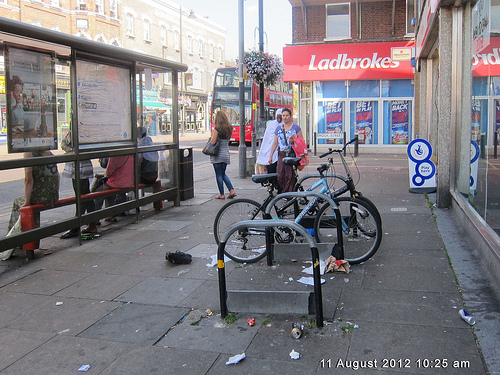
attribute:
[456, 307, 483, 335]
bottle — empty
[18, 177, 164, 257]
stage seat — red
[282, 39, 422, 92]
awning — red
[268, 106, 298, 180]
people — waiting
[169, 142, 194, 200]
trash can — black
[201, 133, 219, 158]
bag — brown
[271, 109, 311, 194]
woman — carrying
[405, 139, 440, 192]
display — outdoor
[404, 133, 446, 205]
sign — blue, white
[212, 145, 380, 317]
rack — bike rack, gray, black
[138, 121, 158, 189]
person — waiting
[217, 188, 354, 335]
bicycle rack — black, silver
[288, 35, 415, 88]
sign — red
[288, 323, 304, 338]
can — aluminum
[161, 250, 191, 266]
paper — black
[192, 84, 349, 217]
people — walking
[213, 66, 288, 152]
bus — red, big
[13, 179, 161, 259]
bench — red